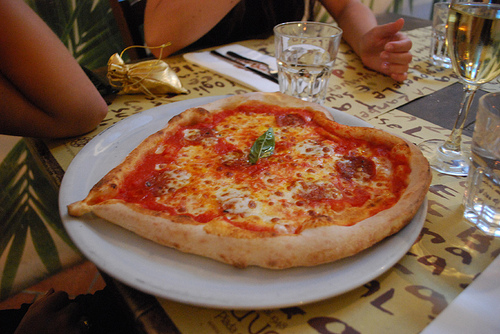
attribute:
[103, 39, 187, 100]
bag — gold 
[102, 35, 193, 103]
bag — gold, little, golden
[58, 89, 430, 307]
white plate — is white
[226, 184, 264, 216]
cheese — melted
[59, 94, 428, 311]
plate — is white, white 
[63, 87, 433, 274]
pizza — heart shaped, deformed 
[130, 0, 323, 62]
dress — is black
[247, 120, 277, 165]
oregano — leaf 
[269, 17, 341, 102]
cup — little